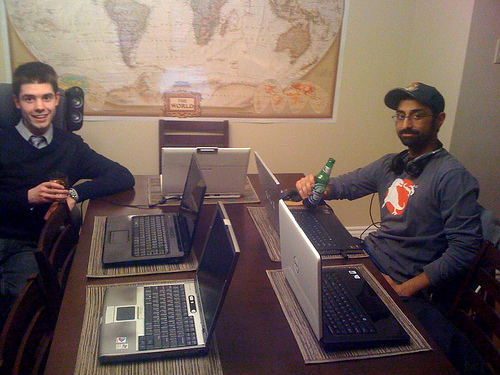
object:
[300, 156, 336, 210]
beer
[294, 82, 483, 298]
person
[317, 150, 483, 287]
shirt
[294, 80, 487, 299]
man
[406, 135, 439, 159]
neck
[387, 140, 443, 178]
headphones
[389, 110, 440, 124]
eyeglasses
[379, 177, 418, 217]
dinosaur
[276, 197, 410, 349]
laptop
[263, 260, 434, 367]
placemat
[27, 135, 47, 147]
tie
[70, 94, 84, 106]
speaker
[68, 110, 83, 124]
speaker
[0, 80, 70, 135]
chair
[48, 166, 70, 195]
glass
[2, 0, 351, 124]
map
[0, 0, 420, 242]
wall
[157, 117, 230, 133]
tip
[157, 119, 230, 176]
chair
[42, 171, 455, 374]
table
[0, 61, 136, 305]
man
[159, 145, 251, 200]
laptop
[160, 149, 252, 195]
lid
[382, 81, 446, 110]
cap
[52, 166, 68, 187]
drink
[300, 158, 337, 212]
beer bottle